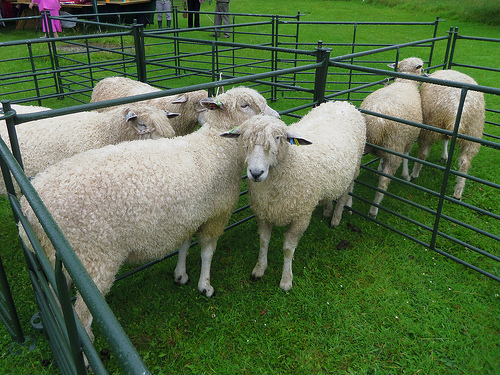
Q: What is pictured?
A: Sheep.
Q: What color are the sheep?
A: White.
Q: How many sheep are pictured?
A: 6.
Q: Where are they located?
A: In pins.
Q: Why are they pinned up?
A: So they don't run away.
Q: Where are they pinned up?
A: Outside in the grass.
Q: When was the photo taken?
A: Daylight hours.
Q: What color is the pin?
A: Green.